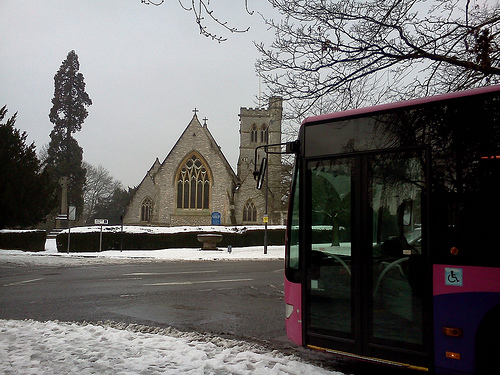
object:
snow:
[6, 245, 287, 259]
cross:
[191, 106, 200, 115]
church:
[106, 96, 298, 229]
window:
[249, 122, 258, 143]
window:
[261, 124, 268, 144]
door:
[210, 212, 220, 225]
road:
[2, 253, 305, 374]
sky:
[2, 4, 477, 107]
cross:
[202, 115, 208, 123]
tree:
[45, 48, 90, 231]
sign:
[94, 216, 106, 224]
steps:
[43, 228, 66, 257]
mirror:
[251, 152, 271, 192]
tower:
[239, 90, 283, 216]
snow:
[104, 342, 157, 373]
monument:
[53, 174, 71, 229]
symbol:
[444, 266, 464, 286]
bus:
[282, 80, 497, 374]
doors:
[300, 150, 433, 374]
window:
[175, 150, 213, 209]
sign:
[260, 216, 270, 223]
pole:
[264, 144, 270, 254]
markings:
[147, 278, 254, 286]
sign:
[438, 268, 476, 297]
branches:
[166, 0, 499, 92]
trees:
[190, 6, 500, 114]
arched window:
[173, 148, 213, 214]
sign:
[212, 210, 227, 226]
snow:
[0, 318, 325, 371]